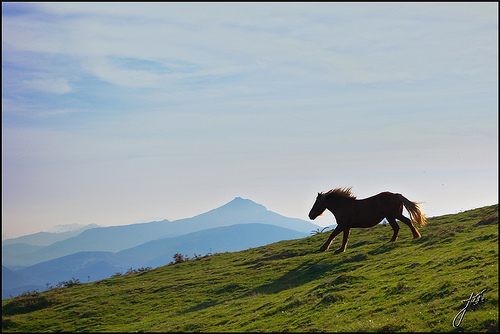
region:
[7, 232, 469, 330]
fields are lush and green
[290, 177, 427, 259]
a horse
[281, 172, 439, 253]
a horse running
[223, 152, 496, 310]
a horse running down a hill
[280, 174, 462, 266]
a brown horse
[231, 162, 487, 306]
a brown horse running on grass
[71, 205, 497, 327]
a grassy hillside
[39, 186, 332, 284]
mountains in distance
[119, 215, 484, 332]
the grass is green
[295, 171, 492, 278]
the horse is running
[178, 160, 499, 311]
the horse casts a shadow as it runs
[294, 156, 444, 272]
brown horse is running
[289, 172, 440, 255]
horse galloping through field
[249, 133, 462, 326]
horse galloping through field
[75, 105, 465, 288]
horse running free on the land.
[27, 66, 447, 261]
elegant horse running free on the land.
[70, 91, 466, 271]
attractive horse running free on the land.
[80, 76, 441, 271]
amazing horse running free on the land.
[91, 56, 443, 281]
beautiful horse running free on the land.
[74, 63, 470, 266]
healthy horse running free on the land.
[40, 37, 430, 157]
a patch of beautiful sky.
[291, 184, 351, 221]
the head of a horse.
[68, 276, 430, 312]
green stretch of land.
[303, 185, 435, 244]
An animal in a field.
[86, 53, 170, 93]
A cloud in the sky.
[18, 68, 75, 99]
A cloud in the sky.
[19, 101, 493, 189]
A cloud in the sky.